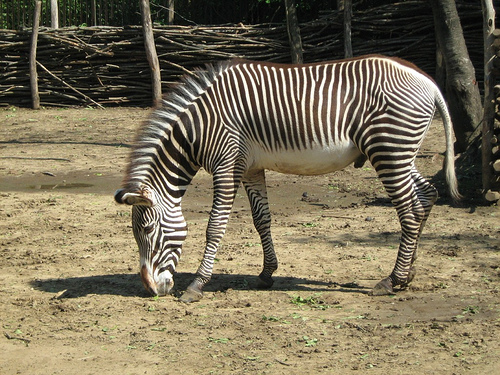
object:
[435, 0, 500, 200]
trunk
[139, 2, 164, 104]
tree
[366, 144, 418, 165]
stripe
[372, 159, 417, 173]
stripe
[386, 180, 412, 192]
stripe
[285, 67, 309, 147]
stripe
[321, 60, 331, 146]
stripe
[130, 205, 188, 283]
face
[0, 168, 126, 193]
puddle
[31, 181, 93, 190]
water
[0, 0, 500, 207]
sticks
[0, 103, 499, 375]
ground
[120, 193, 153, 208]
ear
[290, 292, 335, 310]
grass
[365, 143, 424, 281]
back leg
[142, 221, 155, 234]
eye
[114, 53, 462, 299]
animal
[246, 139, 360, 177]
belly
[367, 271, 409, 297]
hoof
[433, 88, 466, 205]
tail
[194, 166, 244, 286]
front leg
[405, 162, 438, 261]
back legs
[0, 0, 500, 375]
zoo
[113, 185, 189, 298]
head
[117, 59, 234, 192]
mane